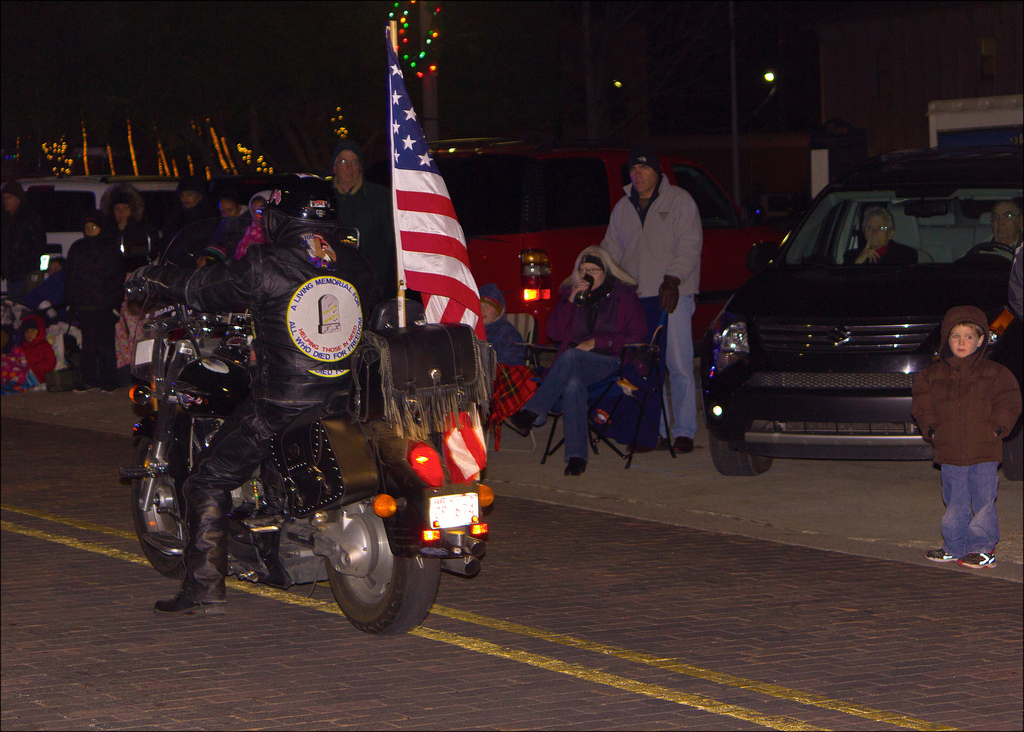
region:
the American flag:
[354, 15, 511, 385]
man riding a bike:
[111, 221, 489, 662]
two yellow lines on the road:
[441, 586, 768, 726]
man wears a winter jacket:
[590, 131, 721, 457]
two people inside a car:
[768, 175, 1022, 283]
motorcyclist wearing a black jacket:
[148, 166, 406, 457]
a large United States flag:
[350, 20, 499, 499]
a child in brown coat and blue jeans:
[911, 298, 1023, 587]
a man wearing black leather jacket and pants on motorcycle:
[131, 183, 492, 658]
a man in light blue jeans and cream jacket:
[580, 148, 713, 475]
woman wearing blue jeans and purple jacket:
[523, 238, 688, 494]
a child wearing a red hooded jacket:
[7, 305, 72, 403]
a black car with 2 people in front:
[699, 140, 1023, 494]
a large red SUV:
[383, 122, 796, 443]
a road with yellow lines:
[2, 415, 1018, 730]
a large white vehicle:
[14, 166, 193, 275]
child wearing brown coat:
[906, 305, 1018, 575]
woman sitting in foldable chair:
[510, 245, 679, 477]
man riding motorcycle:
[114, 187, 498, 633]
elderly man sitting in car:
[693, 150, 1022, 477]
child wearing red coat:
[0, 313, 58, 402]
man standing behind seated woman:
[498, 144, 705, 478]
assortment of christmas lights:
[1, 112, 278, 183]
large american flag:
[371, 35, 517, 507]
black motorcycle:
[86, 195, 507, 661]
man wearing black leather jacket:
[83, 130, 535, 647]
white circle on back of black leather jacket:
[276, 266, 363, 377]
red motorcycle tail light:
[396, 437, 457, 498]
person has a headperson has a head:
[261, 204, 301, 244]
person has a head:
[574, 248, 603, 287]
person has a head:
[630, 157, 660, 199]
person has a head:
[859, 205, 898, 247]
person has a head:
[946, 311, 984, 359]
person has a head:
[480, 292, 503, 327]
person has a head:
[340, 147, 361, 186]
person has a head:
[176, 178, 196, 205]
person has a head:
[217, 192, 240, 213]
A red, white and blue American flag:
[367, 4, 500, 343]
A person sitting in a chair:
[485, 226, 704, 496]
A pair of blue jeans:
[920, 443, 1010, 562]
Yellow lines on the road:
[0, 478, 978, 722]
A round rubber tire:
[311, 526, 449, 647]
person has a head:
[216, 183, 243, 216]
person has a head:
[175, 180, 201, 206]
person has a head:
[103, 192, 132, 227]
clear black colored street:
[0, 412, 1019, 723]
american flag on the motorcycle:
[384, 45, 493, 343]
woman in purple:
[519, 242, 650, 474]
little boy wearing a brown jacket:
[912, 307, 1010, 571]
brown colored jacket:
[912, 298, 1014, 466]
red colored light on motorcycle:
[397, 430, 456, 484]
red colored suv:
[422, 137, 806, 352]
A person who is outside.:
[901, 308, 999, 561]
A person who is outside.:
[603, 133, 734, 443]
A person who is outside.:
[527, 260, 646, 483]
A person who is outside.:
[470, 283, 551, 429]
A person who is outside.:
[296, 137, 427, 324]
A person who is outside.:
[206, 187, 255, 268]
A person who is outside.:
[135, 178, 208, 287]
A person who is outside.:
[98, 197, 165, 303]